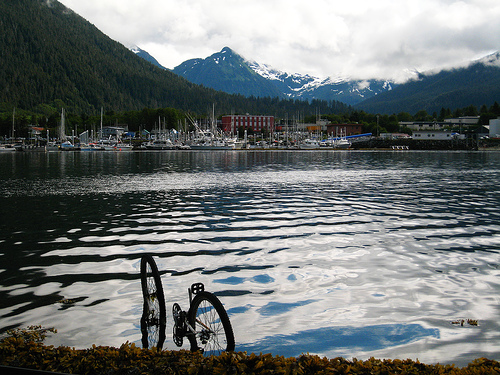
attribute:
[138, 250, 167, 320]
wheel — exposed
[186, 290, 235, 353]
wheel — exposed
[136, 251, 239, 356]
bike — upside down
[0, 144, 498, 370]
water — rippling